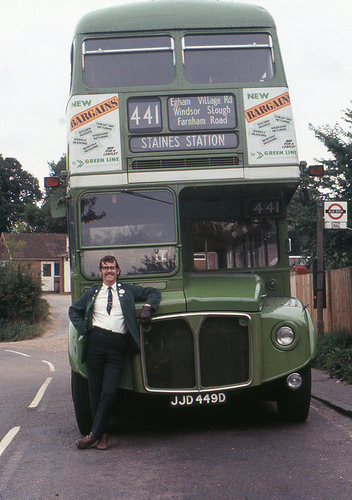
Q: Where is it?
A: This is at the road.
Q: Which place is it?
A: It is a road.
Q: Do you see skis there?
A: No, there are no skis.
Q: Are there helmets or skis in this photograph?
A: No, there are no skis or helmets.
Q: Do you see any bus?
A: Yes, there is a bus.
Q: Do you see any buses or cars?
A: Yes, there is a bus.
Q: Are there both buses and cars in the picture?
A: No, there is a bus but no cars.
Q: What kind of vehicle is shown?
A: The vehicle is a bus.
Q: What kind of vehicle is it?
A: The vehicle is a bus.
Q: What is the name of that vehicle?
A: This is a bus.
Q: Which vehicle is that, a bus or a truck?
A: This is a bus.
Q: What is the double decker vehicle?
A: The vehicle is a bus.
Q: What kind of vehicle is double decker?
A: The vehicle is a bus.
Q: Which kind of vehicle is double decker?
A: The vehicle is a bus.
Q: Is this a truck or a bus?
A: This is a bus.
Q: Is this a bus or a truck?
A: This is a bus.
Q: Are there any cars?
A: No, there are no cars.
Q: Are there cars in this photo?
A: No, there are no cars.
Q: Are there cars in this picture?
A: No, there are no cars.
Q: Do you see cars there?
A: No, there are no cars.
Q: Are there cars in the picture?
A: No, there are no cars.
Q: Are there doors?
A: Yes, there is a door.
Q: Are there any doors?
A: Yes, there is a door.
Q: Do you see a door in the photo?
A: Yes, there is a door.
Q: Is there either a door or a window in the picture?
A: Yes, there is a door.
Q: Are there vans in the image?
A: No, there are no vans.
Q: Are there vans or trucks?
A: No, there are no vans or trucks.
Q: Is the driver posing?
A: Yes, the driver is posing.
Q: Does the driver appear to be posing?
A: Yes, the driver is posing.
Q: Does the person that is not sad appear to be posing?
A: Yes, the driver is posing.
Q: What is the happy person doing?
A: The driver is posing.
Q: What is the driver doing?
A: The driver is posing.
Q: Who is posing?
A: The driver is posing.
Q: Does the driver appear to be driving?
A: No, the driver is posing.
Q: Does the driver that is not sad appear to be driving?
A: No, the driver is posing.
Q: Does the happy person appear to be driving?
A: No, the driver is posing.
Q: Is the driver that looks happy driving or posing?
A: The driver is posing.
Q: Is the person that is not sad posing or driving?
A: The driver is posing.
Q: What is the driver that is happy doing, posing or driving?
A: The driver is posing.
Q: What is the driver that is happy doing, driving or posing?
A: The driver is posing.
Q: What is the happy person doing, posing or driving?
A: The driver is posing.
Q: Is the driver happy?
A: Yes, the driver is happy.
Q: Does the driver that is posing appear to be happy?
A: Yes, the driver is happy.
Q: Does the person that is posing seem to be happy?
A: Yes, the driver is happy.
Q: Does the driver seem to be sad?
A: No, the driver is happy.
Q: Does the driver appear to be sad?
A: No, the driver is happy.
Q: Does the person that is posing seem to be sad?
A: No, the driver is happy.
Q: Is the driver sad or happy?
A: The driver is happy.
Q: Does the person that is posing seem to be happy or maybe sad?
A: The driver is happy.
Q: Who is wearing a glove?
A: The driver is wearing a glove.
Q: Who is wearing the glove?
A: The driver is wearing a glove.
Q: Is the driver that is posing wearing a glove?
A: Yes, the driver is wearing a glove.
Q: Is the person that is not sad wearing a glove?
A: Yes, the driver is wearing a glove.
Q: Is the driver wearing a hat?
A: No, the driver is wearing a glove.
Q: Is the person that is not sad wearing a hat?
A: No, the driver is wearing a glove.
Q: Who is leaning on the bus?
A: The driver is leaning on the bus.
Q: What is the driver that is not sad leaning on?
A: The driver is leaning on the bus.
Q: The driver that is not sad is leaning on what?
A: The driver is leaning on the bus.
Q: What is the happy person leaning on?
A: The driver is leaning on the bus.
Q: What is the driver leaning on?
A: The driver is leaning on the bus.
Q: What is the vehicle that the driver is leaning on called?
A: The vehicle is a bus.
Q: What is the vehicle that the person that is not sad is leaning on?
A: The vehicle is a bus.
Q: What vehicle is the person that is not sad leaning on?
A: The driver is leaning on the bus.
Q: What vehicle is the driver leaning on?
A: The driver is leaning on the bus.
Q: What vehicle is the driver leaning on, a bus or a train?
A: The driver is leaning on a bus.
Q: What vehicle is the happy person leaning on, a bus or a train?
A: The driver is leaning on a bus.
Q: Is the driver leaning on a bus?
A: Yes, the driver is leaning on a bus.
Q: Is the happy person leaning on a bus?
A: Yes, the driver is leaning on a bus.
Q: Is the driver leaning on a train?
A: No, the driver is leaning on a bus.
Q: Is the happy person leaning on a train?
A: No, the driver is leaning on a bus.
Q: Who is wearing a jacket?
A: The driver is wearing a jacket.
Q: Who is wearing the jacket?
A: The driver is wearing a jacket.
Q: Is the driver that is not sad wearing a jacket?
A: Yes, the driver is wearing a jacket.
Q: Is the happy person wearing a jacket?
A: Yes, the driver is wearing a jacket.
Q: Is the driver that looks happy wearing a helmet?
A: No, the driver is wearing a jacket.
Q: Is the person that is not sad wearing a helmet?
A: No, the driver is wearing a jacket.